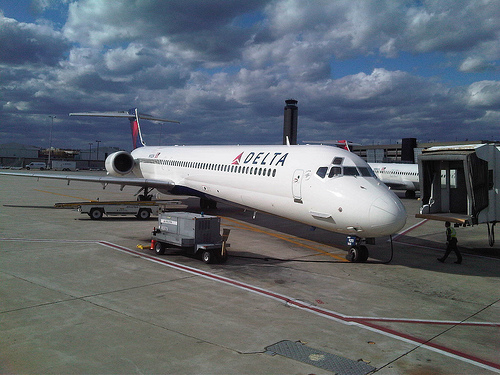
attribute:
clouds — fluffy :
[70, 11, 495, 116]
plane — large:
[2, 107, 407, 262]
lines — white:
[233, 282, 353, 325]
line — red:
[92, 236, 484, 372]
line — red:
[346, 309, 479, 331]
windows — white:
[216, 165, 276, 178]